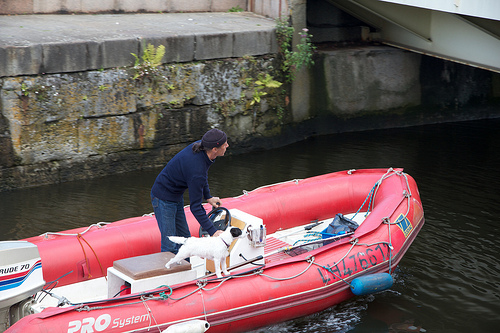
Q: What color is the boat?
A: Red.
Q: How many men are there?
A: 1.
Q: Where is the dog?
A: On the boat.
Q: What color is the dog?
A: White and black.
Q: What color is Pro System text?
A: White.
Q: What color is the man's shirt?
A: Blue.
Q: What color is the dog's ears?
A: Black.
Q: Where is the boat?
A: In the water.